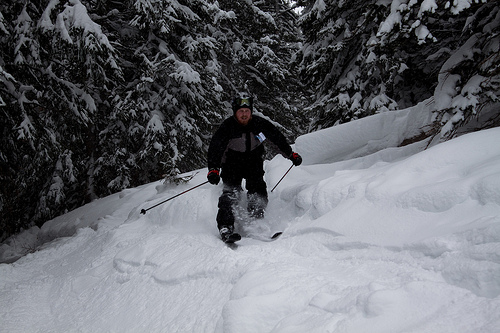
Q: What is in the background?
A: Trees.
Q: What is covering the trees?
A: Snow.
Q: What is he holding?
A: Ski poles.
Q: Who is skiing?
A: A man.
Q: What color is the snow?
A: White.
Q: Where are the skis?
A: In the snow.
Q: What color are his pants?
A: Black.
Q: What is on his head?
A: Hat.